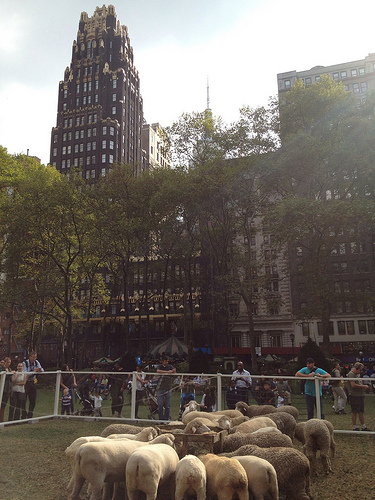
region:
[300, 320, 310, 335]
narrow building window with black frame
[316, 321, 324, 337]
narrow building window with black frame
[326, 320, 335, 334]
narrow building window with black frame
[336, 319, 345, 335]
narrow building window with black frame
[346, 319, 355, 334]
narrow building window with black frame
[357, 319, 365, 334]
narrow building window with black frame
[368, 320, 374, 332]
narrow building window with black frame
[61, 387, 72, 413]
small blond child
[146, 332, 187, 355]
black and tan tent top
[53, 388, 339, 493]
Sheep Feeding in a feed trough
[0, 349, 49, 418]
Family watching the sheep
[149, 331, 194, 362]
Blue and white awning over the building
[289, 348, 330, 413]
Guy with a blue shirt watching sheep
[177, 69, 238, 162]
Church Steeple behind the trees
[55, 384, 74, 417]
Boy in striped shirt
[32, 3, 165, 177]
Beautiful old building with many floors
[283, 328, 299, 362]
Lamp Post Along the street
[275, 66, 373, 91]
9 windows on the top floor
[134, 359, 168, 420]
Woman pushing baby stroller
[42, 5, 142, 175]
A black and gold building.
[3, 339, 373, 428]
A group of people in front of a fence.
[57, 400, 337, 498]
A bunch of sheep eating.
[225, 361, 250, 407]
A man and his daughter looking at sheep.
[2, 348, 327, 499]
A group of people watching the sheep eat.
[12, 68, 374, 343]
Buildings shaded by trees.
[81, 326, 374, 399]
A line of vendors near the buildings.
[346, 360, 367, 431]
A man with headphones on.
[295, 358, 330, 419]
A man in a light blue shirt and a hat.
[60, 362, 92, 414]
A woman with her child and a stroller.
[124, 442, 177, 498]
off white sheered sheep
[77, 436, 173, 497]
off white sheered sheep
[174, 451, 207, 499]
off white sheered sheep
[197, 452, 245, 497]
off white sheered sheep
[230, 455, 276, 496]
off white sheered sheep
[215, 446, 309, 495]
dirty off white sheep unsheered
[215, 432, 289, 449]
off white sheered sheep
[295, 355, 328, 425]
man with hat watching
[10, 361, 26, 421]
short woman watching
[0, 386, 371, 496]
green and yellow grass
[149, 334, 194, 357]
Brown and black umbrella tarp in the background.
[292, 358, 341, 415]
Man standing watching sheep in blue shirt.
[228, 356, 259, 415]
Man in white shirt watching sheep.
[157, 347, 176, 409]
Man in black t-shirt looking to the right.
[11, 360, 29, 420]
Girl in white shirt standing between a man and woman.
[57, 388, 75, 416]
Small baby in striped t-shirt.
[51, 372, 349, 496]
Sheep in the center of the photo.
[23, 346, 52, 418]
Man wearing a back pack standing beside little girl in white shirt.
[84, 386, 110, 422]
Baby in white shirt standing in front of stroller.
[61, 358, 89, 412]
Woman standing behind the little baby wearing a striped shirt.